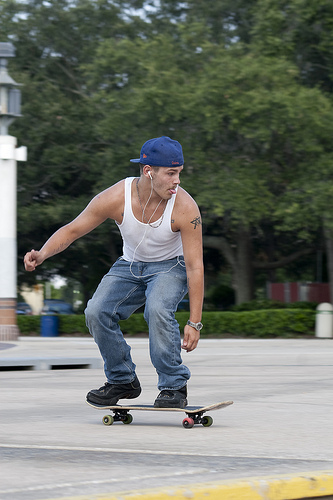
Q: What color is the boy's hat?
A: Blue.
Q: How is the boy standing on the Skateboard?
A: He is balancing.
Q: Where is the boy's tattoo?
A: On his left shoulder.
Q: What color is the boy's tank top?
A: White.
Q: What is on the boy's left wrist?
A: A watch.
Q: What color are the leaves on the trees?
A: Green.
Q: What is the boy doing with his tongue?
A: Sticking it out.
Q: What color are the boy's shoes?
A: Black.